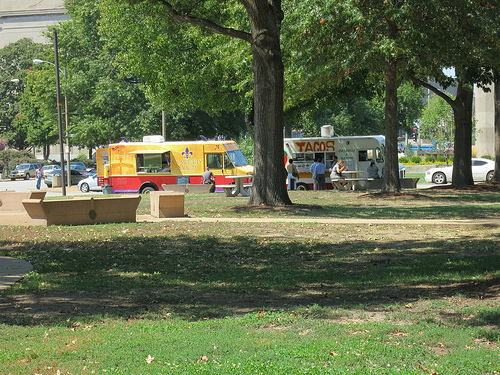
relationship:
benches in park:
[25, 172, 234, 260] [75, 51, 269, 227]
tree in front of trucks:
[229, 67, 302, 212] [95, 124, 406, 194]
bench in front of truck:
[150, 185, 200, 220] [96, 135, 255, 194]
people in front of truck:
[283, 147, 369, 205] [96, 135, 255, 194]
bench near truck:
[149, 189, 186, 218] [96, 135, 255, 194]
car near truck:
[428, 150, 491, 193] [96, 135, 255, 194]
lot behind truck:
[25, 143, 126, 220] [89, 111, 271, 212]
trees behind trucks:
[218, 64, 477, 220] [95, 124, 406, 194]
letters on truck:
[293, 131, 348, 162] [96, 135, 255, 194]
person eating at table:
[329, 156, 346, 185] [328, 169, 372, 192]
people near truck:
[285, 158, 327, 190] [96, 135, 255, 194]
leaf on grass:
[145, 354, 155, 364] [0, 186, 500, 340]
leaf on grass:
[198, 352, 212, 363] [0, 186, 500, 340]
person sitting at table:
[328, 160, 351, 191] [342, 170, 366, 192]